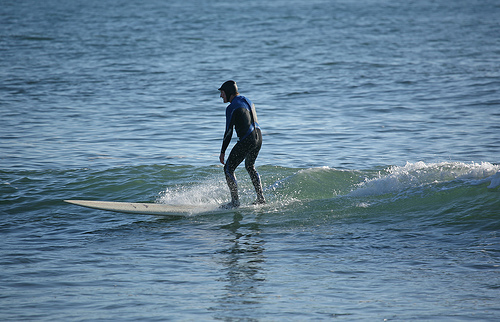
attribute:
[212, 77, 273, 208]
wet suit — blue, black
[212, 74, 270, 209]
man — riding, wearing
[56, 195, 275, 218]
surfboard — white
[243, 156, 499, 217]
wave — small, low, coming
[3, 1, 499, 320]
water — dark blue, calm, splashing, ocean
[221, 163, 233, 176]
knee — bent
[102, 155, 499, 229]
waves — gentle